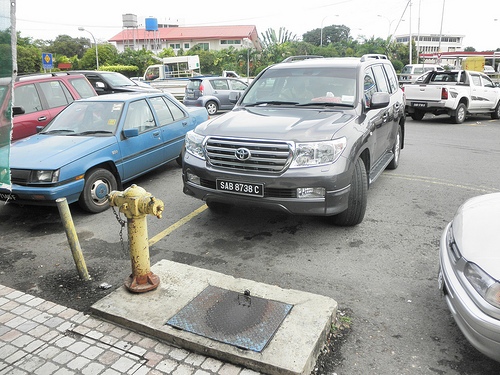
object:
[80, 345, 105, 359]
tile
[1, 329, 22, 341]
tile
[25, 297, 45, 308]
tiles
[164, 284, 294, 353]
manhole cover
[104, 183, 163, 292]
fire hydrant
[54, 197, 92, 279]
stop pole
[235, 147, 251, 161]
logo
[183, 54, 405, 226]
suv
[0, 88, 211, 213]
car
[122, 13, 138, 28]
water tank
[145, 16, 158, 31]
water tank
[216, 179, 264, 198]
license plate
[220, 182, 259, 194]
writing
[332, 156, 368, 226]
wheel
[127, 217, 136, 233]
rust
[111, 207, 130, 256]
chain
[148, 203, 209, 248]
line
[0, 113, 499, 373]
ground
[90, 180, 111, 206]
hubcap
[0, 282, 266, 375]
sidewalk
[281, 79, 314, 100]
man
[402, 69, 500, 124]
truck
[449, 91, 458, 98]
marks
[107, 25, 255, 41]
roof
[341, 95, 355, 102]
sticker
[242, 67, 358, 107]
windshield